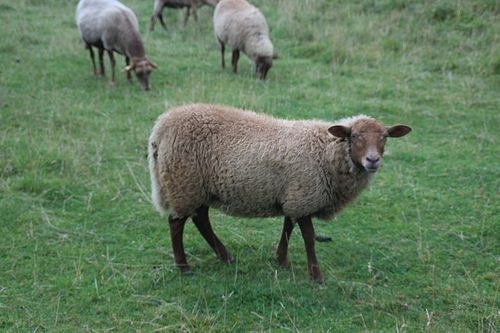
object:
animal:
[146, 101, 413, 285]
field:
[0, 0, 500, 333]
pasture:
[0, 0, 500, 333]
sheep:
[75, 0, 167, 92]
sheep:
[212, 0, 282, 81]